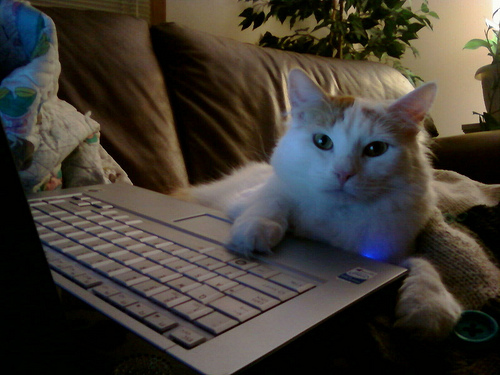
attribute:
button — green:
[455, 303, 488, 344]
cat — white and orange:
[177, 57, 479, 342]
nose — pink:
[329, 145, 364, 190]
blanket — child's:
[1, 0, 133, 197]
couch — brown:
[1, 5, 497, 372]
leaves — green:
[267, 7, 397, 48]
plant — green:
[240, 0, 426, 66]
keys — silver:
[97, 224, 217, 335]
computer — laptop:
[2, 119, 410, 374]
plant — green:
[463, 0, 499, 67]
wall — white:
[161, 3, 498, 143]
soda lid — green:
[449, 309, 494, 346]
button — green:
[448, 305, 497, 345]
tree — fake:
[237, 0, 442, 89]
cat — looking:
[170, 65, 465, 332]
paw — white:
[226, 214, 286, 256]